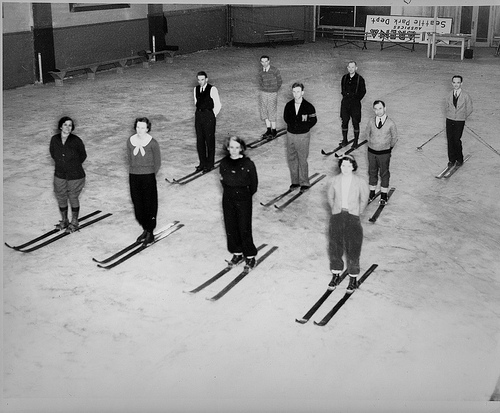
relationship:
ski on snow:
[297, 156, 415, 337] [257, 223, 427, 375]